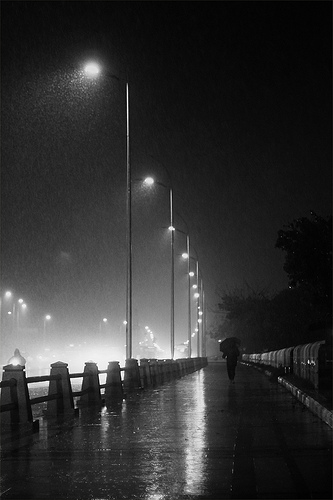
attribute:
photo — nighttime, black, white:
[1, 1, 332, 499]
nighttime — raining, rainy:
[4, 1, 332, 500]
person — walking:
[221, 348, 243, 378]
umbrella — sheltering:
[220, 334, 253, 357]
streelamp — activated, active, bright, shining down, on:
[80, 59, 136, 406]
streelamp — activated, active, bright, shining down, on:
[142, 173, 178, 370]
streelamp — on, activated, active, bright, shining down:
[165, 218, 197, 367]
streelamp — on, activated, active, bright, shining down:
[184, 260, 205, 367]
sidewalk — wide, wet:
[0, 351, 331, 500]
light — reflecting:
[137, 360, 210, 499]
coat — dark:
[220, 349, 243, 378]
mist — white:
[7, 71, 204, 364]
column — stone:
[1, 364, 41, 441]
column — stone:
[41, 359, 80, 424]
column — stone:
[78, 363, 104, 410]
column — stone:
[106, 362, 127, 406]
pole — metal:
[20, 373, 54, 410]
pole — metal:
[69, 369, 91, 409]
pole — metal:
[96, 364, 113, 403]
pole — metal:
[122, 360, 132, 390]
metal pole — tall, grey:
[119, 85, 137, 363]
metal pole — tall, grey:
[165, 189, 180, 357]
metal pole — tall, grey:
[186, 236, 197, 363]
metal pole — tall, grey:
[192, 257, 202, 367]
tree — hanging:
[281, 210, 332, 346]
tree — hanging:
[221, 285, 295, 350]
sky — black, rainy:
[2, 0, 331, 355]